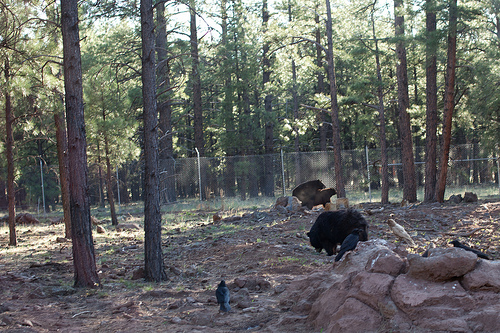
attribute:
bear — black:
[315, 203, 358, 238]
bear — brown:
[289, 180, 328, 200]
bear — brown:
[299, 182, 338, 207]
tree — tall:
[126, 50, 181, 282]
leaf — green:
[93, 32, 116, 73]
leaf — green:
[78, 53, 105, 75]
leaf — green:
[76, 42, 95, 63]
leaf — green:
[93, 76, 107, 103]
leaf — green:
[78, 43, 100, 58]